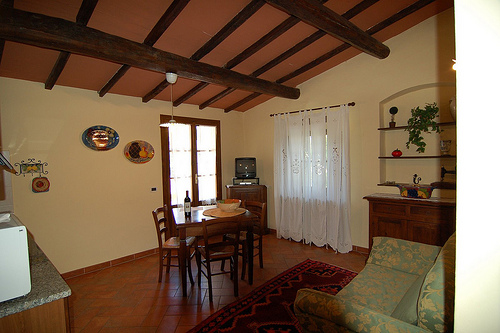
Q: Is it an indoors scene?
A: Yes, it is indoors.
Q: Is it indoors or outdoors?
A: It is indoors.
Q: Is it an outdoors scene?
A: No, it is indoors.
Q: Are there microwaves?
A: Yes, there is a microwave.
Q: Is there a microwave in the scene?
A: Yes, there is a microwave.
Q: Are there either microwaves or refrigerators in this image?
A: Yes, there is a microwave.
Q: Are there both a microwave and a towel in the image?
A: No, there is a microwave but no towels.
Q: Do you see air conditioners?
A: No, there are no air conditioners.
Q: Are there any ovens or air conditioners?
A: No, there are no air conditioners or ovens.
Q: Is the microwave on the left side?
A: Yes, the microwave is on the left of the image.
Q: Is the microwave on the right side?
A: No, the microwave is on the left of the image.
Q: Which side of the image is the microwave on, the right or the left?
A: The microwave is on the left of the image.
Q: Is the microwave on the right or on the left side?
A: The microwave is on the left of the image.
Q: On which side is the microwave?
A: The microwave is on the left of the image.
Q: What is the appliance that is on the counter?
A: The appliance is a microwave.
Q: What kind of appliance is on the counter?
A: The appliance is a microwave.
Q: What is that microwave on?
A: The microwave is on the counter.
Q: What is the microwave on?
A: The microwave is on the counter.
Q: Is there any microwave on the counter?
A: Yes, there is a microwave on the counter.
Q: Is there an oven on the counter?
A: No, there is a microwave on the counter.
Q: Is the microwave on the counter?
A: Yes, the microwave is on the counter.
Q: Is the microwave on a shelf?
A: No, the microwave is on the counter.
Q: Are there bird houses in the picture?
A: No, there are no bird houses.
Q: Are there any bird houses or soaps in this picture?
A: No, there are no bird houses or soaps.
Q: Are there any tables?
A: Yes, there is a table.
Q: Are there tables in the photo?
A: Yes, there is a table.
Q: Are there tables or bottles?
A: Yes, there is a table.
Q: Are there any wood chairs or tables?
A: Yes, there is a wood table.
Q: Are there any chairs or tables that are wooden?
A: Yes, the table is wooden.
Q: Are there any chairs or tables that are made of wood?
A: Yes, the table is made of wood.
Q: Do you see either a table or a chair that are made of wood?
A: Yes, the table is made of wood.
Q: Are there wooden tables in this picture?
A: Yes, there is a wood table.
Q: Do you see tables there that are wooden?
A: Yes, there is a table that is wooden.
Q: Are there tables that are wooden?
A: Yes, there is a table that is wooden.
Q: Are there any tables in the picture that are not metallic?
A: Yes, there is a wooden table.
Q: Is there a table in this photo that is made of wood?
A: Yes, there is a table that is made of wood.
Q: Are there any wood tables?
A: Yes, there is a table that is made of wood.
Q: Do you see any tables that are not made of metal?
A: Yes, there is a table that is made of wood.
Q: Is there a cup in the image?
A: No, there are no cups.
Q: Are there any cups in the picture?
A: No, there are no cups.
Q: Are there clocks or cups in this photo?
A: No, there are no cups or clocks.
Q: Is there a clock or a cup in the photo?
A: No, there are no cups or clocks.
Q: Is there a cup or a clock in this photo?
A: No, there are no cups or clocks.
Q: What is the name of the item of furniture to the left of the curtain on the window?
A: The piece of furniture is a table.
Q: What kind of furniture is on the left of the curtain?
A: The piece of furniture is a table.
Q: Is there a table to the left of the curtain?
A: Yes, there is a table to the left of the curtain.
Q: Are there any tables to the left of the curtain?
A: Yes, there is a table to the left of the curtain.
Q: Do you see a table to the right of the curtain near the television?
A: No, the table is to the left of the curtain.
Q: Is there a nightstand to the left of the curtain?
A: No, there is a table to the left of the curtain.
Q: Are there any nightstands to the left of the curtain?
A: No, there is a table to the left of the curtain.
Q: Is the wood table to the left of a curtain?
A: Yes, the table is to the left of a curtain.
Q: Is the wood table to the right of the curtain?
A: No, the table is to the left of the curtain.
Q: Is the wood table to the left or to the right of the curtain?
A: The table is to the left of the curtain.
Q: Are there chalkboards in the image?
A: No, there are no chalkboards.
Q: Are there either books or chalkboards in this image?
A: No, there are no chalkboards or books.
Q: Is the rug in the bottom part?
A: Yes, the rug is in the bottom of the image.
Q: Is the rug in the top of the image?
A: No, the rug is in the bottom of the image.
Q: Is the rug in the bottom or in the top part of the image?
A: The rug is in the bottom of the image.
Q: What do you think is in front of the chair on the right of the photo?
A: The rug is in front of the chair.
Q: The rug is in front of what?
A: The rug is in front of the chair.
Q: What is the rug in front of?
A: The rug is in front of the chair.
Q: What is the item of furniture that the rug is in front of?
A: The piece of furniture is a chair.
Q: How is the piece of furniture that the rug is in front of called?
A: The piece of furniture is a chair.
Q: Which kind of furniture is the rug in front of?
A: The rug is in front of the chair.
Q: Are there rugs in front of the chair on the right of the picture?
A: Yes, there is a rug in front of the chair.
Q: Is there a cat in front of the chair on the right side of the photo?
A: No, there is a rug in front of the chair.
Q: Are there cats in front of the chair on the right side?
A: No, there is a rug in front of the chair.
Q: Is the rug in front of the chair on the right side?
A: Yes, the rug is in front of the chair.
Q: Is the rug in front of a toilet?
A: No, the rug is in front of the chair.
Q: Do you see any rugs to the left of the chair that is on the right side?
A: Yes, there is a rug to the left of the chair.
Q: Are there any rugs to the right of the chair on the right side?
A: No, the rug is to the left of the chair.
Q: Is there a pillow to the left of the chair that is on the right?
A: No, there is a rug to the left of the chair.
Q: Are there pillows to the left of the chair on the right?
A: No, there is a rug to the left of the chair.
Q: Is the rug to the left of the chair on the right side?
A: Yes, the rug is to the left of the chair.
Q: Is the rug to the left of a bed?
A: No, the rug is to the left of the chair.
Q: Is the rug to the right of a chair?
A: No, the rug is to the left of a chair.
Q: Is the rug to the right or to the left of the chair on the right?
A: The rug is to the left of the chair.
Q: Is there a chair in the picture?
A: Yes, there is a chair.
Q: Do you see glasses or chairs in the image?
A: Yes, there is a chair.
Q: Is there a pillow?
A: No, there are no pillows.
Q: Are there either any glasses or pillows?
A: No, there are no pillows or glasses.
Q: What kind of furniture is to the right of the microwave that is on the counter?
A: The piece of furniture is a chair.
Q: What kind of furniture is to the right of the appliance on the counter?
A: The piece of furniture is a chair.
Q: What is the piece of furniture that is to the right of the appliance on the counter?
A: The piece of furniture is a chair.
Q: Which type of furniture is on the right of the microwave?
A: The piece of furniture is a chair.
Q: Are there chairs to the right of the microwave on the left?
A: Yes, there is a chair to the right of the microwave.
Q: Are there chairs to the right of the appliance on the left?
A: Yes, there is a chair to the right of the microwave.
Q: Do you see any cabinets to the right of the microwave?
A: No, there is a chair to the right of the microwave.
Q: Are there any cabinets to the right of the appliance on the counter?
A: No, there is a chair to the right of the microwave.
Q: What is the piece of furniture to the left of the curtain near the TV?
A: The piece of furniture is a chair.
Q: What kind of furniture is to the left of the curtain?
A: The piece of furniture is a chair.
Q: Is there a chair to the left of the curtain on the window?
A: Yes, there is a chair to the left of the curtain.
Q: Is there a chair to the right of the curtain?
A: No, the chair is to the left of the curtain.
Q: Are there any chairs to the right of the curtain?
A: No, the chair is to the left of the curtain.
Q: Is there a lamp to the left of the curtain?
A: No, there is a chair to the left of the curtain.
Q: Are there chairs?
A: Yes, there is a chair.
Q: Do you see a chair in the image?
A: Yes, there is a chair.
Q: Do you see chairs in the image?
A: Yes, there is a chair.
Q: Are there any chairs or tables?
A: Yes, there is a chair.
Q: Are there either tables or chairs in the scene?
A: Yes, there is a chair.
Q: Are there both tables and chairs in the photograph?
A: Yes, there are both a chair and a table.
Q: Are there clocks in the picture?
A: No, there are no clocks.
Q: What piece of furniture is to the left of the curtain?
A: The piece of furniture is a chair.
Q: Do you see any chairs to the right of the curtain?
A: No, the chair is to the left of the curtain.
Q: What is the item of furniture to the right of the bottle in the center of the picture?
A: The piece of furniture is a chair.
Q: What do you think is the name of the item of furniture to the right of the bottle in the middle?
A: The piece of furniture is a chair.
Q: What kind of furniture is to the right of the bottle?
A: The piece of furniture is a chair.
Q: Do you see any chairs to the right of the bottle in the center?
A: Yes, there is a chair to the right of the bottle.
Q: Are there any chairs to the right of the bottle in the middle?
A: Yes, there is a chair to the right of the bottle.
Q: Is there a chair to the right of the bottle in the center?
A: Yes, there is a chair to the right of the bottle.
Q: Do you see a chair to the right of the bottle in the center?
A: Yes, there is a chair to the right of the bottle.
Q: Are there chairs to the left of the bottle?
A: No, the chair is to the right of the bottle.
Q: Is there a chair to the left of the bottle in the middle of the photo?
A: No, the chair is to the right of the bottle.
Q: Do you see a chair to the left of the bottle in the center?
A: No, the chair is to the right of the bottle.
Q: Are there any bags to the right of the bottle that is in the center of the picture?
A: No, there is a chair to the right of the bottle.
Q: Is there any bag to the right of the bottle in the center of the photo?
A: No, there is a chair to the right of the bottle.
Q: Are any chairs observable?
A: Yes, there is a chair.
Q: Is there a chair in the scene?
A: Yes, there is a chair.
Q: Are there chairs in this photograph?
A: Yes, there is a chair.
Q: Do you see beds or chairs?
A: Yes, there is a chair.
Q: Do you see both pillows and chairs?
A: No, there is a chair but no pillows.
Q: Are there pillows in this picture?
A: No, there are no pillows.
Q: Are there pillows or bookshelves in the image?
A: No, there are no pillows or bookshelves.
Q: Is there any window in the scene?
A: Yes, there is a window.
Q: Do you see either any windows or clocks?
A: Yes, there is a window.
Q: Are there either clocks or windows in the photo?
A: Yes, there is a window.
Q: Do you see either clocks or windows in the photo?
A: Yes, there is a window.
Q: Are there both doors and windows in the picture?
A: No, there is a window but no doors.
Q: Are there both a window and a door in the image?
A: No, there is a window but no doors.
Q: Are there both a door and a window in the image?
A: No, there is a window but no doors.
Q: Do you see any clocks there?
A: No, there are no clocks.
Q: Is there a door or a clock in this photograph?
A: No, there are no clocks or doors.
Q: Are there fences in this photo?
A: No, there are no fences.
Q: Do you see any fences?
A: No, there are no fences.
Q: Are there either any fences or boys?
A: No, there are no fences or boys.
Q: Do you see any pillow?
A: No, there are no pillows.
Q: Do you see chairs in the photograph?
A: Yes, there is a chair.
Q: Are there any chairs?
A: Yes, there is a chair.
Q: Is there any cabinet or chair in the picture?
A: Yes, there is a chair.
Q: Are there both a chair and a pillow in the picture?
A: No, there is a chair but no pillows.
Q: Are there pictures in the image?
A: No, there are no pictures.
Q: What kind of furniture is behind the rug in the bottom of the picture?
A: The piece of furniture is a chair.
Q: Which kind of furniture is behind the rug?
A: The piece of furniture is a chair.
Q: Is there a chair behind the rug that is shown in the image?
A: Yes, there is a chair behind the rug.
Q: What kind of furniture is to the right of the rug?
A: The piece of furniture is a chair.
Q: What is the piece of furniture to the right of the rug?
A: The piece of furniture is a chair.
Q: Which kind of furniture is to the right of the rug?
A: The piece of furniture is a chair.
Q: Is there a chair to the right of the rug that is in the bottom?
A: Yes, there is a chair to the right of the rug.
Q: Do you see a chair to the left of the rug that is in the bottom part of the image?
A: No, the chair is to the right of the rug.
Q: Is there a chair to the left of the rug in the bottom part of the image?
A: No, the chair is to the right of the rug.